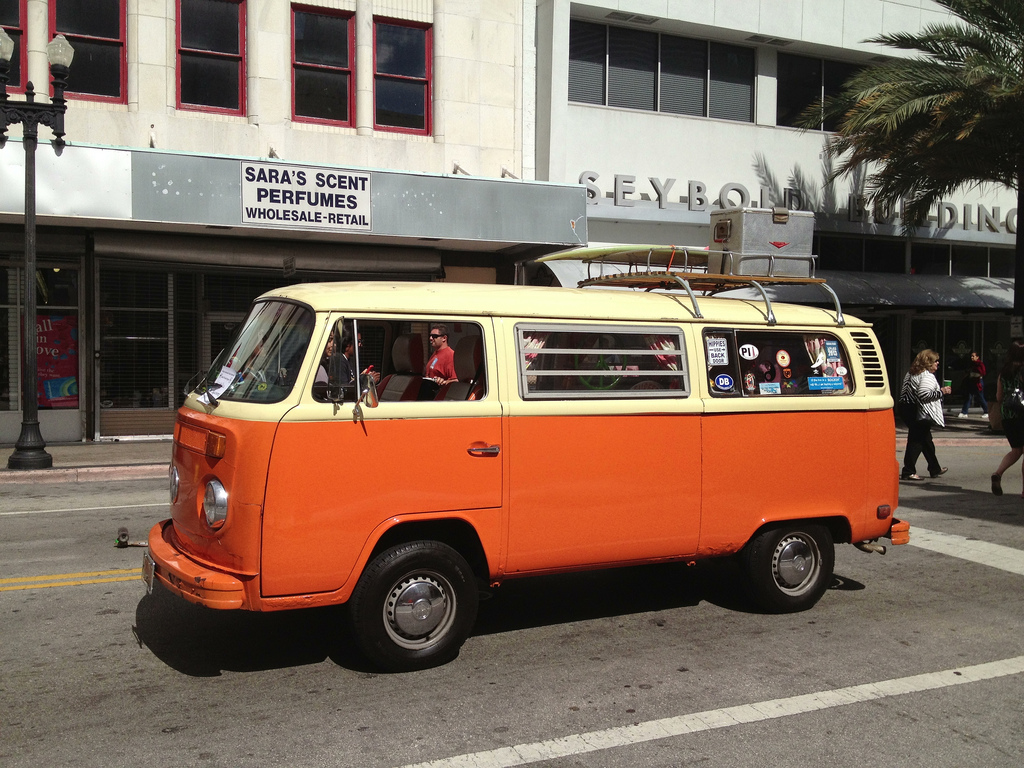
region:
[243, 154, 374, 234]
business sign on the front of the building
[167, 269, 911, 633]
orange van parked in the street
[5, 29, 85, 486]
lamp post on the side walk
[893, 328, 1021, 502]
people walking in the street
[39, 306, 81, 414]
sign in the shop window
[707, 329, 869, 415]
stickers on the van window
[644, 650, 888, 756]
white line painted in the road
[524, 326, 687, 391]
curtains in the van window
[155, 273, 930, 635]
orange and yellow van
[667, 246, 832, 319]
brown and silver rack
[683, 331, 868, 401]
numerous stickers on window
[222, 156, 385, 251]
black and white sign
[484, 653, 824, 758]
road is light grey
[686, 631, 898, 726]
white line on road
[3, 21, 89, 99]
two lights on pole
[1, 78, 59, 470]
black and metal pole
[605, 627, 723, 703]
grease stains on street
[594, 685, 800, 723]
white line on the street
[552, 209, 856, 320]
rack on top of van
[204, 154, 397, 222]
large white sign on top of store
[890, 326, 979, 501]
woman walking on the street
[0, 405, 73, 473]
base of black street lamp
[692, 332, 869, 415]
stickers on side of van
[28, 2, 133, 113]
a window on a building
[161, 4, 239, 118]
a window on a building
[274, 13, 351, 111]
a window on a building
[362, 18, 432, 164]
a window on a building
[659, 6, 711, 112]
a window on a building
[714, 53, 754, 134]
a window on a building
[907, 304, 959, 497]
a person walking on a street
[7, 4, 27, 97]
a window on a building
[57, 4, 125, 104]
a window on a building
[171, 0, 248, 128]
a window on a building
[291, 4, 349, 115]
a window on a building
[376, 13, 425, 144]
a window on a building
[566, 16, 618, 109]
a window on a building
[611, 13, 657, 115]
a window on a building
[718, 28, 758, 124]
a window on a building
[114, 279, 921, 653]
a car on a street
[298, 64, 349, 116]
glass is clear and clean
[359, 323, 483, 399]
glass is clear and clean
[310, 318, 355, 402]
glass is clear and clean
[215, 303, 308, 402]
glass is clear and clean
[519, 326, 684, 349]
glass is clear and clean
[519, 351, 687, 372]
glass is clear and clean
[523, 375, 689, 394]
glass is clear and clean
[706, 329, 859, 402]
glass is clear and clean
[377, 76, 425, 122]
glass is clear and clean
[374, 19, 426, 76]
glass is clear and clean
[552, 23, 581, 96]
a window on the building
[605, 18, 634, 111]
a window on the building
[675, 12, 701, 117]
a window on the building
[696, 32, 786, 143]
a window on the building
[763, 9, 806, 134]
a window on the building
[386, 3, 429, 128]
a window on the building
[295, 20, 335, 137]
a window on the building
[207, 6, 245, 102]
a window on the building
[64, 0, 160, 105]
a window on the building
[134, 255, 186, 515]
a window on the building